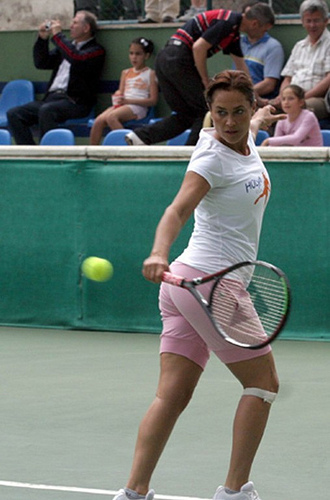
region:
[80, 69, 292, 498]
a female tennis player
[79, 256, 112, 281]
a yellow tennis ball in flight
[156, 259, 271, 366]
a pair of pink shorts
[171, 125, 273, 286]
a woman's white t-shirt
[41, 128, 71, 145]
a blue stadium seat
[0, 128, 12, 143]
a blue stadium seat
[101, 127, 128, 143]
a blue stadium seat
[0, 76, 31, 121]
a blue stadium seat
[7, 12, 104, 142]
a man taking a photograph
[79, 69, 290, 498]
a woman hitting ball backhanded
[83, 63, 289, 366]
a woman hitting a tennis ball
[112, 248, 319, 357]
a tennis racket with a pink handle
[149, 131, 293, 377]
a woman wearing pink shorts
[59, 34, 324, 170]
people sitting in the stands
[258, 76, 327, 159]
a girl with a pink shirt on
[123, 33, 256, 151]
a man with black jeans on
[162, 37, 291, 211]
a woman with red hair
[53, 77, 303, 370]
a woman hitting a green tennis ball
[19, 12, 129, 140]
a man wearing a black jacket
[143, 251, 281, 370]
THE GIRL IS WEARING PINK SHORTS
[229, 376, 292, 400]
THE BAND IS ON THE GIRL'S KNEE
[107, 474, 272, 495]
THE GIRL IS WEARING WHITE SHIRTS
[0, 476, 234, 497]
THE WHITE LINE IS PAINTED ON THE GROUND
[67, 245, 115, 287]
THE BALL IS YELLOW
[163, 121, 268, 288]
THE GIRLS T-SHIRT IS WHITE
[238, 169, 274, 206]
THE LOGO IS ON THE GIRL'S SHIRT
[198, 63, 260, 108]
THE WOMAN HAS BROWN HAIR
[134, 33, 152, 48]
THE GIRL IS WEARING A BOW IN HER HAIR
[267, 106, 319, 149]
THE GIRL IS WEARING A PINK SHIRT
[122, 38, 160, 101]
a girl sitting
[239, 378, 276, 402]
white band on the leg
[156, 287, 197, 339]
pink shorts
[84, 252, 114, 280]
a green tennis ball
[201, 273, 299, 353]
a tennis racket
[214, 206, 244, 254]
the shirt is white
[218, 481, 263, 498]
the women is wearing a white shoe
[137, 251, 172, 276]
the women is holding a tennis racket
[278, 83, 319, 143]
a girl sitting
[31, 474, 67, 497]
white line on the court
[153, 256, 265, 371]
a woman wearing pink shorts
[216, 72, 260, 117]
a woman with brown hair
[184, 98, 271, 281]
a woman wearing a white shirt with a logo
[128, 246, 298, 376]
a woman holding a tennis racket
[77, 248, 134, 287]
a yellow tennis ball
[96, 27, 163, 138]
a young girl sitting in the bleachers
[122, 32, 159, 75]
a young girl with a white hair bow in her hair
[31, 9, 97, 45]
a man holding a camera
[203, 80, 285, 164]
a woman with her arm stretched out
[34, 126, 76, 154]
a blue chair